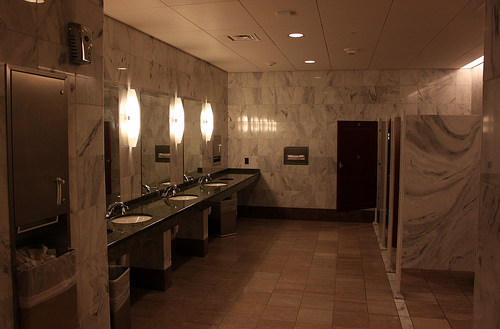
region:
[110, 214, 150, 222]
One of the three wash basins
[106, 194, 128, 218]
Faucet on one of the wash basins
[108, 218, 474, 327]
The tiles on the floor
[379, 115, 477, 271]
Partitions between the urinals in a row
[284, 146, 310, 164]
Paper napkin dispenser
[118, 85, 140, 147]
One of the three lights above the wash basins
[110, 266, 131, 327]
One of the dustbins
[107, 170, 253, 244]
The granite countertop around the wash basins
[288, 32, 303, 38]
One of the recessed ceiling lights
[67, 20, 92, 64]
Air refresher fitted in the male toilet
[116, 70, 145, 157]
light on bathroom wall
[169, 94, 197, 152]
light on bathroom wall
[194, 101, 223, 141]
light on bathroom wall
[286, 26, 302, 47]
light on bathroom ceiling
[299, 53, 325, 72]
light on bathroom ceiling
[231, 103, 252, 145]
reflection of light in marble wall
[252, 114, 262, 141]
reflection of light in marble wall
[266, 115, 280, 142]
reflection of light in marble wall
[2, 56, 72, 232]
metal paper towel dispenser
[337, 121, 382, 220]
open bathroom stall door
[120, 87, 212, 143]
three modern lamps on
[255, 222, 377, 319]
an impeccable brown floor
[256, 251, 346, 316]
a brown clean tiles floor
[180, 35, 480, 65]
the bathroom white ceiling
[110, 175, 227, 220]
three white clean washbasin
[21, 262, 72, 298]
a transparent bag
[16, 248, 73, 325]
the trash can garbage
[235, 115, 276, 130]
the light reflected on the wall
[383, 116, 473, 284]
soem toilet areas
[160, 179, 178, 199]
one washbasin faucet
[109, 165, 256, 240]
Line of three sinks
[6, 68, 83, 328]
Paper towel dispenser and trash bin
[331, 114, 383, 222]
Black door with silver handle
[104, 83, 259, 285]
Three sinks and three mirrors on wall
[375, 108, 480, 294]
Line of bathroom stalls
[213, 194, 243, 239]
Trash can lined with plastic bag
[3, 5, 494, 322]
White and gray marble bathroom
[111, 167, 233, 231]
Three sinks with silver faucets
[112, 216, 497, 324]
Floor covered with brown tile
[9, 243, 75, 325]
Trash can filled with white paper towels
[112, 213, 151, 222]
a white porcelain bathroom sink basin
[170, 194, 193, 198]
a white porcelain bathroom sink basin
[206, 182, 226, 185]
a white porcelain bathroom sink basin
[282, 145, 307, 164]
a wall mounted paper dispenser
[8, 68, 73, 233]
a paper towel dispenser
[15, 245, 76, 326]
a lined trash can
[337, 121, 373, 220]
a closed black door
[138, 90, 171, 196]
a wall mounted vanity mirror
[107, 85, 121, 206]
a wall mounted vanity mirror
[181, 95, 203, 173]
a wall mounted vanity mirror